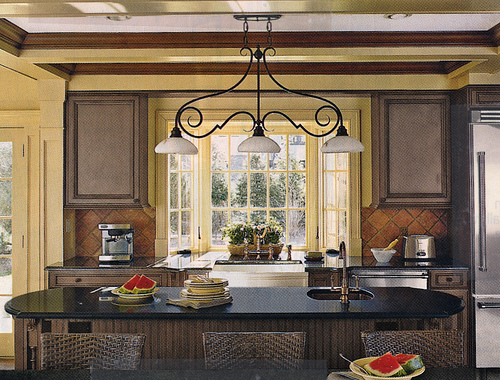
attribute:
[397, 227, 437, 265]
toaster — silver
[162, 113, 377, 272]
window — wooden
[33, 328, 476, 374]
chairs — woven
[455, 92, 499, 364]
refrigerator — silver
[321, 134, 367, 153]
light bulb — white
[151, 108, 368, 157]
light — white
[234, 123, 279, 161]
light — white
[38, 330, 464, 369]
chairs — wicker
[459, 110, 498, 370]
fridge — gray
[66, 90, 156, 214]
wooden shelf — brown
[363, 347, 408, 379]
watermelon — big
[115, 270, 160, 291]
watermelon — slice , big 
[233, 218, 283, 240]
plant — potted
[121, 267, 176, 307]
watermelon — big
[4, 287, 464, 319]
counter top — black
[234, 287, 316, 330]
table — black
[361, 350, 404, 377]
watermelon — big , slice 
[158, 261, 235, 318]
plates — stack 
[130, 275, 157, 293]
watermelon — sliced 